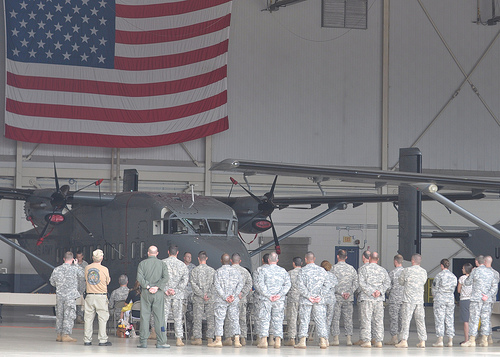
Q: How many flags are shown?
A: One.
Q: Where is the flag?
A: On wall.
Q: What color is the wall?
A: White.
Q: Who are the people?
A: Soldiers.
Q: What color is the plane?
A: Gray.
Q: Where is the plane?
A: On floor.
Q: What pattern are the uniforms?
A: Camouflage.